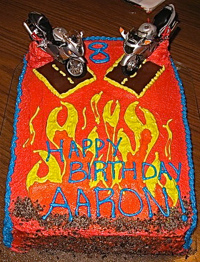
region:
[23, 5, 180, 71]
two motorcycle toy in the cake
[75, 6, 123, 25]
wooden plywood of the table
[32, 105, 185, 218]
cream made design of the cake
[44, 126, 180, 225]
text written on the cake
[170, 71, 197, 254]
blue color cream border of the cake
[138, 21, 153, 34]
fuel tank of the motor cycle toy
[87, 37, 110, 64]
number 8 written in the cake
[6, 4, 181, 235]
a cake kept in the brown color table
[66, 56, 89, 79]
wheel of the toy motor cycle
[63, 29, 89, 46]
handle bar of the toy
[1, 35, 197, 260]
Big red birthday sheetcake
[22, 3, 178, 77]
Toy motorcycles sitting on the top of a cake as decoration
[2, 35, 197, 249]
Bright blue cake icing outlilng a cake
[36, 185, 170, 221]
The word AARON in bright blue icing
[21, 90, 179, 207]
Yellow icing drawn on a cake to look like flames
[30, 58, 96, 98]
Brown chocolate icing with a yellow border, made to look like a road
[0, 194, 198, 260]
Choclate sprinkles on the bottome of a cake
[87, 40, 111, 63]
Number 8 in bright blue cake icing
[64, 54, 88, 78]
Front wheel of a silver toy motorcycle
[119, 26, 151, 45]
Orange and white side mirrors on a toy motorcycle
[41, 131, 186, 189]
happy birthday writing on cake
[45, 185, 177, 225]
a boys name on cake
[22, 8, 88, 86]
motorcycle on a cake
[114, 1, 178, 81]
motorcycle on a cake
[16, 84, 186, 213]
red yellow and blue cake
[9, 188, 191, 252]
brown stuff on cake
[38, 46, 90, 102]
part of a road on cake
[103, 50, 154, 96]
part of a road on cake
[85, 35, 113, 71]
the birthday boy turns 8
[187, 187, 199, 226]
Blue edging on cake.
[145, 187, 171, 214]
Blue N on cake.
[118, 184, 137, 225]
Blue O on cake.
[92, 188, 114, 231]
Blue R on cake.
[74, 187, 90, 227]
Blue A on cake.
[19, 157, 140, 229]
Red frosting on top of cake.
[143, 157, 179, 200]
Yellow frosting on top of cake.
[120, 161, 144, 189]
Blue H on top of cake.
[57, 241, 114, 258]
Brown side of cake.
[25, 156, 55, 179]
Yellow frosting on top of cake.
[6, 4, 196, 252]
close-up of a birthday cake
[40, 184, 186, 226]
name of the birthday boy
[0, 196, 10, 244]
blue frosting trim on the cake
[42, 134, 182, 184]
greeting written in blue frosting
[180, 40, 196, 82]
table top where the cake is set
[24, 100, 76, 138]
yellow decorative frosting on a red background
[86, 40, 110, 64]
age of the birthday boy in blue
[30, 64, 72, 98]
lines in the road in frosting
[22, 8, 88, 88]
toy motorcycle on the cake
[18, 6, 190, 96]
two bikes set on a birthday cake